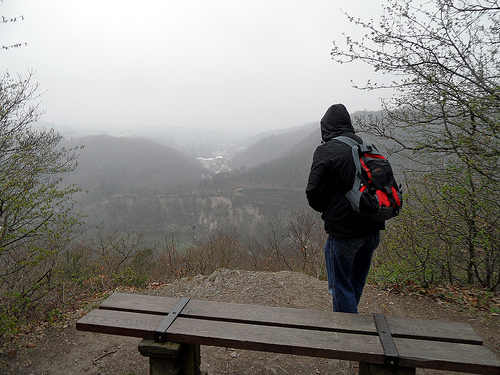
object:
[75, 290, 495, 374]
bench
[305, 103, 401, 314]
person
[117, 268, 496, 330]
ledge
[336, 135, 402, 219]
backpack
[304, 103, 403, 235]
jacket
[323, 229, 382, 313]
jeans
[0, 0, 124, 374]
tree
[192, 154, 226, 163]
water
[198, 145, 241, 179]
town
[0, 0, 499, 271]
distance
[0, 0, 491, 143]
sky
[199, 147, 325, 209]
hillside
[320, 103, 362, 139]
hood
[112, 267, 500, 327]
cliff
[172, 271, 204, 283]
rocks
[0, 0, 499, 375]
day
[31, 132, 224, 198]
mountain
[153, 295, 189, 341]
brace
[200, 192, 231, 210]
snow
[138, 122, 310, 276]
valley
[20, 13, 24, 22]
bud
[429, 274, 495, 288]
leaf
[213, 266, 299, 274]
edge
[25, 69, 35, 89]
branch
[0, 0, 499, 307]
fog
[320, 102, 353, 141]
head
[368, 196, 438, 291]
brush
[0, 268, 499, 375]
pathway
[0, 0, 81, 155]
top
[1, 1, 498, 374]
photo